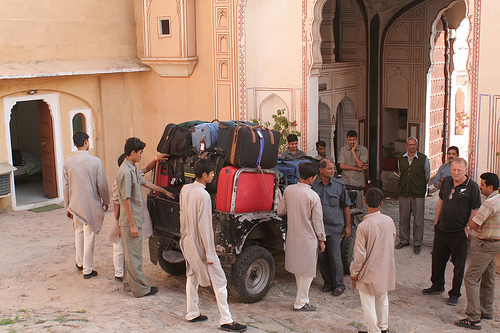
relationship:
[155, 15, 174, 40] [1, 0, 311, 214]
window on wall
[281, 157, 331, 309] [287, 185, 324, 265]
man in shirt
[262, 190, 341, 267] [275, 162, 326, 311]
shirt of man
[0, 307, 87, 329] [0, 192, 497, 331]
grass on ground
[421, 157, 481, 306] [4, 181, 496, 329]
man in street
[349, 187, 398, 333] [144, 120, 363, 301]
man standing near jeep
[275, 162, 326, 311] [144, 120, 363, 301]
man standing near jeep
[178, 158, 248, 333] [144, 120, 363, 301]
man standing near jeep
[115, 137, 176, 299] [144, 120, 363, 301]
man standing near jeep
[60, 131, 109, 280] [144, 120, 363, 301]
man standing near jeep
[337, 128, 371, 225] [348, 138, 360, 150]
man has hand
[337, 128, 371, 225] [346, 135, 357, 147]
man has face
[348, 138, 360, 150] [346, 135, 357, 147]
hand touching face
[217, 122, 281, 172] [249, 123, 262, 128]
suitcase with handle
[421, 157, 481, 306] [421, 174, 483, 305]
man with black clothing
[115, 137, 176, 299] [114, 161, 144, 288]
man in coveralls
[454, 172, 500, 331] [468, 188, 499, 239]
man wearing shirt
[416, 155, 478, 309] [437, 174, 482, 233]
man wearing black clothing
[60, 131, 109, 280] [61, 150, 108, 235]
man wearing tan shirt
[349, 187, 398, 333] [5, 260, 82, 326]
man in street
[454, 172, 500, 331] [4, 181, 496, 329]
man in street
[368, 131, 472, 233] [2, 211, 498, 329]
man standing in street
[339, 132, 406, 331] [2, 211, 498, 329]
man standing in street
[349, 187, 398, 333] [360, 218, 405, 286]
man wears beige shirt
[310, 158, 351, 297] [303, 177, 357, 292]
man wearing gray clothing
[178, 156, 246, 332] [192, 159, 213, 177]
man with black hair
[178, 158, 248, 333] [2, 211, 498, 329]
man standing in street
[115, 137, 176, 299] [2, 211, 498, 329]
man standing in street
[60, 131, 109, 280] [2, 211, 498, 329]
man standing in street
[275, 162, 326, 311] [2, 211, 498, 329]
man standing in street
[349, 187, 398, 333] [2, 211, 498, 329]
man standing in street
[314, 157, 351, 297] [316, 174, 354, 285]
man wearing uniform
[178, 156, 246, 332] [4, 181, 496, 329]
man standing in street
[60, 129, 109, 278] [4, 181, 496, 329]
man standing in street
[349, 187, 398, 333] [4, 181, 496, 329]
man standing in street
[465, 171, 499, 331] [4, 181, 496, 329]
man standing in street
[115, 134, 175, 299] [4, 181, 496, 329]
man standing in street